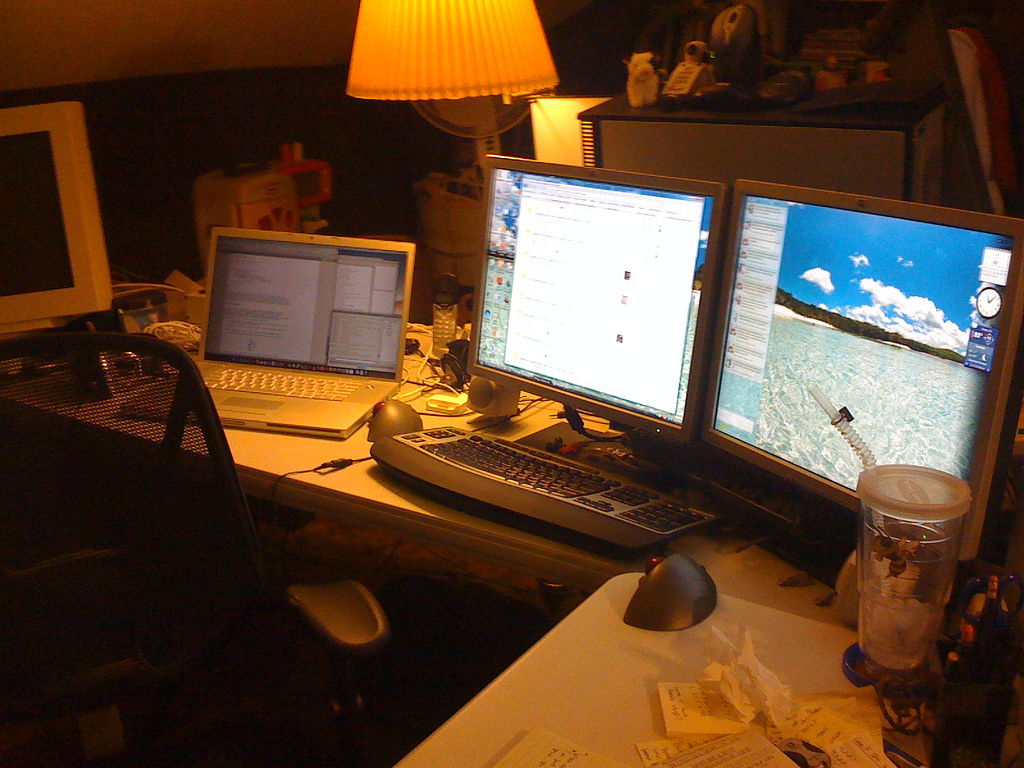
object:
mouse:
[624, 554, 717, 631]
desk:
[2, 280, 861, 630]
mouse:
[369, 401, 424, 442]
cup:
[841, 449, 975, 682]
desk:
[389, 570, 1022, 767]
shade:
[347, 0, 558, 100]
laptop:
[120, 224, 418, 440]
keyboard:
[369, 427, 719, 553]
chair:
[0, 330, 388, 768]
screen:
[0, 100, 112, 335]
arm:
[288, 581, 390, 654]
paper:
[655, 677, 751, 737]